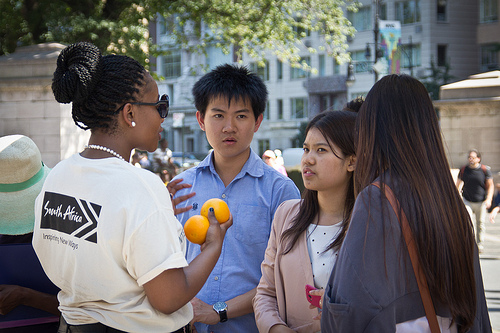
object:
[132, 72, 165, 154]
face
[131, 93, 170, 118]
sunglasses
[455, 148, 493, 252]
person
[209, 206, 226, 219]
orange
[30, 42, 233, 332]
lady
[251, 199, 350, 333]
shirt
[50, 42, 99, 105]
braids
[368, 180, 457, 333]
bag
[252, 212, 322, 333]
beige cardigan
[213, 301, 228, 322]
watch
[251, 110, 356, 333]
lady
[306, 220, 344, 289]
shirt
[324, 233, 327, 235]
dot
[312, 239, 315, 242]
dot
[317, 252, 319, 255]
dot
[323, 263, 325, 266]
dot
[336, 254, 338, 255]
dot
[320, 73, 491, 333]
lady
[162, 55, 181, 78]
window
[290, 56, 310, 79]
window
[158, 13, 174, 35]
window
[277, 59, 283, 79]
window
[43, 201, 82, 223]
letters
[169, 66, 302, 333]
man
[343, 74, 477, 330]
black hair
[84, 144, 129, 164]
pearls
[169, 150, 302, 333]
shirt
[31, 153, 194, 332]
shirt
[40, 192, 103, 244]
picture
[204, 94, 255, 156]
face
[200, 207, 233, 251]
hand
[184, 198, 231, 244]
oranges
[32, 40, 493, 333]
people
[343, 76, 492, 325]
hair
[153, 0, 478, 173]
building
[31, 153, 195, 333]
tee shirt